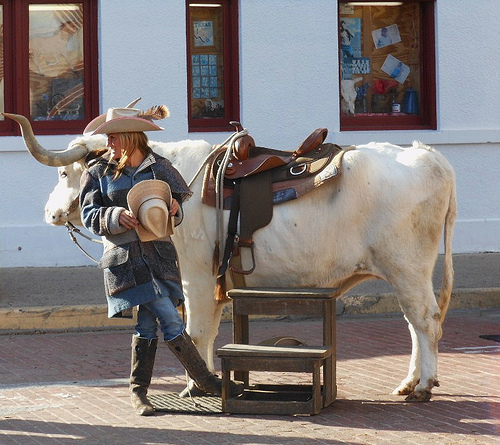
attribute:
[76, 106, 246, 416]
cowgirl — standing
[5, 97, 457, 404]
steer — white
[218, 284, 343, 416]
stool — rickety, wooden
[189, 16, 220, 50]
poster — blue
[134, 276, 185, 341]
jeans — blue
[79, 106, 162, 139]
hat — pink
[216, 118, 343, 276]
saddle — leather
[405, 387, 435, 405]
hoof — brownish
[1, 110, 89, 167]
horn — starp, large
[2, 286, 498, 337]
curb — chipped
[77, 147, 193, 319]
coat — long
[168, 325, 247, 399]
boot — long